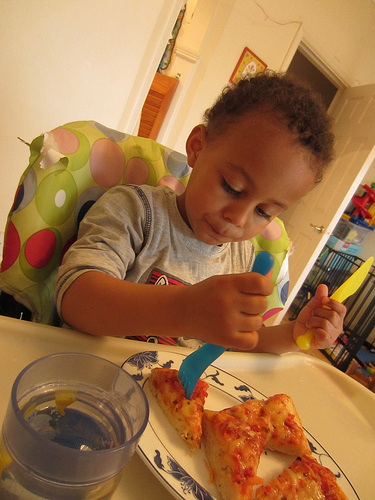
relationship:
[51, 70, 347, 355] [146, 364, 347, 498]
child eating pizza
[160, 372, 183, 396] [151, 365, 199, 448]
sauce on pizza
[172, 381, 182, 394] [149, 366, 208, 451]
sauce on pizza slice